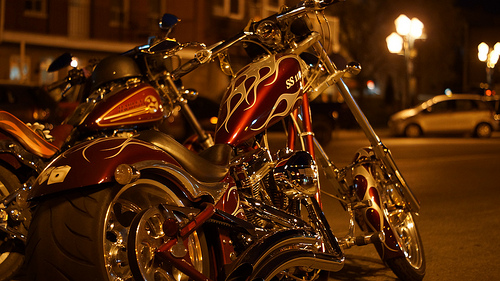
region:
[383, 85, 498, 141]
blurry mini van in the distance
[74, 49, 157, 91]
black motorcycle bucket helmet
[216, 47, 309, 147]
custom gray flame details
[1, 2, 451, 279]
parked motorcycles at night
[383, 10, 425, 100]
blurry street lights in the background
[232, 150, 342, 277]
shiny chrome motorcycle parts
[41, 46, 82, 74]
rear view mirror on a motorcycle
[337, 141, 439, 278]
fancy front tire on custom motorcycle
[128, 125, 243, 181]
black leather motorcycle seat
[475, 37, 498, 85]
street lights off in the distance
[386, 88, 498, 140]
car parked on the street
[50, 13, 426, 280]
red motorcycle parked on the street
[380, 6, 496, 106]
two street lights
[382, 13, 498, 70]
glow of the street lights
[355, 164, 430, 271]
front wheel of motorcycle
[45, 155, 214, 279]
back wheel of motorcycle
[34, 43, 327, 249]
red body of motorcycle with white flame design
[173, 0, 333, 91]
silver handlebars of motorcycle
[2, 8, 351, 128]
buildings along the street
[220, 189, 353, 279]
mufflers on the motorcycle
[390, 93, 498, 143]
a car on the street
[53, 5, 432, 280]
a motorcycle on the street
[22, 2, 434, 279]
the motorcycle is parket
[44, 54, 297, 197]
the motorcycle body is red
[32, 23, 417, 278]
the motorcycle is shining in the streetlight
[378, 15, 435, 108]
the streetlight is on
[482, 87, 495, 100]
a red light behind the car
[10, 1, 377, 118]
a building behind the motorcycle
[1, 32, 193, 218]
another motorcycle left of the first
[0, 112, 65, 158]
an orange section on the motorcycle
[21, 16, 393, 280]
a motorcycle parked on a street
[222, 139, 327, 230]
a chrome engine on a motorcycle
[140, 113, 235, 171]
a black seat on a motorcycle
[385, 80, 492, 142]
a car parked at a curb of a street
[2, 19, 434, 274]
two motorcycles parked on a street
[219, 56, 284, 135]
silver flames painted on a motorcycle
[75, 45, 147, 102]
a black helmet on a motorcycle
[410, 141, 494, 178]
a line painted on a the pavement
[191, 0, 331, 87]
handle bars on a motorcycle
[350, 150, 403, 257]
a painted fender on a motorcycle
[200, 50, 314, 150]
A motorcycle gas tank with emblazoned flames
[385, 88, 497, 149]
A gray van parked at the curb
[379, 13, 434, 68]
The tops of several bright street lights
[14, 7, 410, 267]
A pair of flashy red motorcycles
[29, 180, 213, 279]
The fat back tire of a motorcycle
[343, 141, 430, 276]
The thin front tire of a motorcycle and fender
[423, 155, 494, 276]
A street's gray asphalt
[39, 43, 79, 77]
A rearview mirror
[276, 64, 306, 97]
Lettering on the side of a motorcycle gas tank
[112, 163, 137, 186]
A motorcycle taillight